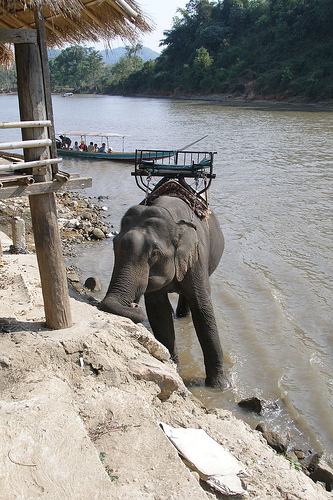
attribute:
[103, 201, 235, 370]
elephant — gray, large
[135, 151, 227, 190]
basket — black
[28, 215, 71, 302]
pole — gray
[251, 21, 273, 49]
tree — green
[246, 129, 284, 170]
river — calm, brown